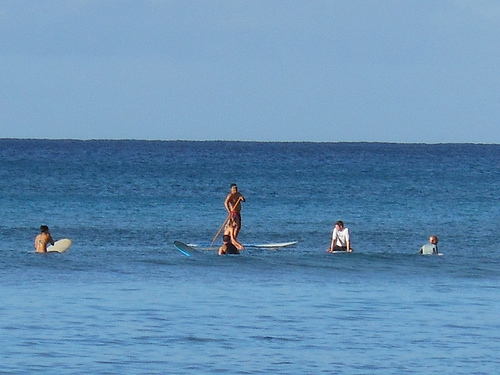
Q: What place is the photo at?
A: It is at the ocean.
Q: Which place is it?
A: It is an ocean.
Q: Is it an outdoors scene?
A: Yes, it is outdoors.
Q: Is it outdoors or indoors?
A: It is outdoors.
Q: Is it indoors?
A: No, it is outdoors.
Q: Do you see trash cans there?
A: No, there are no trash cans.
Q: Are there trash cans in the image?
A: No, there are no trash cans.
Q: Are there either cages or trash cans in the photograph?
A: No, there are no trash cans or cages.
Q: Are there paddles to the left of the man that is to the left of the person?
A: Yes, there is a paddle to the left of the man.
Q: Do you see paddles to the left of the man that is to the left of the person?
A: Yes, there is a paddle to the left of the man.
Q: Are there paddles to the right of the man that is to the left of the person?
A: No, the paddle is to the left of the man.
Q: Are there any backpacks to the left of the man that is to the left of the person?
A: No, there is a paddle to the left of the man.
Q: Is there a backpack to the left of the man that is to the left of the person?
A: No, there is a paddle to the left of the man.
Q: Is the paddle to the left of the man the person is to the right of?
A: Yes, the paddle is to the left of the man.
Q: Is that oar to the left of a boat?
A: No, the oar is to the left of the man.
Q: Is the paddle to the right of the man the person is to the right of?
A: No, the paddle is to the left of the man.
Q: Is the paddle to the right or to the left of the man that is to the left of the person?
A: The paddle is to the left of the man.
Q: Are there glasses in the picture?
A: No, there are no glasses.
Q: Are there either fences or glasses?
A: No, there are no glasses or fences.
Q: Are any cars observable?
A: No, there are no cars.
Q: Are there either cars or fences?
A: No, there are no cars or fences.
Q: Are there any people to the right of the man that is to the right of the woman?
A: Yes, there is a person to the right of the man.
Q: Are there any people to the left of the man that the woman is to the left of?
A: No, the person is to the right of the man.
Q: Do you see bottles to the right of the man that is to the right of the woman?
A: No, there is a person to the right of the man.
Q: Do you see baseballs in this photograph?
A: No, there are no baseballs.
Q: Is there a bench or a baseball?
A: No, there are no baseballs or benches.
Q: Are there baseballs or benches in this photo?
A: No, there are no baseballs or benches.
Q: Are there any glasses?
A: No, there are no glasses.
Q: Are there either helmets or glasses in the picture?
A: No, there are no glasses or helmets.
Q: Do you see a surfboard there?
A: Yes, there is a surfboard.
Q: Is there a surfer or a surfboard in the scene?
A: Yes, there is a surfboard.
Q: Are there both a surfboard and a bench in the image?
A: No, there is a surfboard but no benches.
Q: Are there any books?
A: No, there are no books.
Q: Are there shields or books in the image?
A: No, there are no books or shields.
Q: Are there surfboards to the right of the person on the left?
A: Yes, there is a surfboard to the right of the person.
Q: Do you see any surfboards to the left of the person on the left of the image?
A: No, the surfboard is to the right of the person.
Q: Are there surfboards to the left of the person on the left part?
A: No, the surfboard is to the right of the person.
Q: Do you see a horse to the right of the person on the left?
A: No, there is a surfboard to the right of the person.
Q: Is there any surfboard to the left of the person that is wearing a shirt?
A: Yes, there is a surfboard to the left of the person.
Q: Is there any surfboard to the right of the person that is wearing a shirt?
A: No, the surfboard is to the left of the person.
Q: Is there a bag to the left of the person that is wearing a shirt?
A: No, there is a surfboard to the left of the person.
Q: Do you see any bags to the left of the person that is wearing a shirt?
A: No, there is a surfboard to the left of the person.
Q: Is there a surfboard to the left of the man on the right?
A: Yes, there is a surfboard to the left of the man.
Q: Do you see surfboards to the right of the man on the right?
A: No, the surfboard is to the left of the man.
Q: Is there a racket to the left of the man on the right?
A: No, there is a surfboard to the left of the man.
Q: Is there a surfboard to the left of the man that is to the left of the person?
A: Yes, there is a surfboard to the left of the man.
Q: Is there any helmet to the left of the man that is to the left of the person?
A: No, there is a surfboard to the left of the man.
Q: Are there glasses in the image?
A: No, there are no glasses.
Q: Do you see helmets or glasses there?
A: No, there are no glasses or helmets.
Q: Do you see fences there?
A: No, there are no fences.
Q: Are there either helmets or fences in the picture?
A: No, there are no fences or helmets.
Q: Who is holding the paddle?
A: The man is holding the paddle.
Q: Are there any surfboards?
A: Yes, there is a surfboard.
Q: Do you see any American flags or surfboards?
A: Yes, there is a surfboard.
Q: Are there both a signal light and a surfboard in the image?
A: No, there is a surfboard but no traffic lights.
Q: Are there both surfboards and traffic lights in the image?
A: No, there is a surfboard but no traffic lights.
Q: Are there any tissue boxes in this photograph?
A: No, there are no tissue boxes.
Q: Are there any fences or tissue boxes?
A: No, there are no tissue boxes or fences.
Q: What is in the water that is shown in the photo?
A: The surfboard is in the water.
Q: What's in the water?
A: The surfboard is in the water.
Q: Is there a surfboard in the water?
A: Yes, there is a surfboard in the water.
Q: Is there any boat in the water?
A: No, there is a surfboard in the water.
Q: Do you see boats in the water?
A: No, there is a surfboard in the water.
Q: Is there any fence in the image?
A: No, there are no fences.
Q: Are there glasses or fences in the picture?
A: No, there are no fences or glasses.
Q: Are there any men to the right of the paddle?
A: Yes, there is a man to the right of the paddle.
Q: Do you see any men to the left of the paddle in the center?
A: No, the man is to the right of the oar.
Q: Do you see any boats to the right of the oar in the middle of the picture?
A: No, there is a man to the right of the oar.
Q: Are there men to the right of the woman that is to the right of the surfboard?
A: Yes, there is a man to the right of the woman.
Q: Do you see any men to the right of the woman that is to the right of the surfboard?
A: Yes, there is a man to the right of the woman.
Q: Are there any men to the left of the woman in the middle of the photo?
A: No, the man is to the right of the woman.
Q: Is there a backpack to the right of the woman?
A: No, there is a man to the right of the woman.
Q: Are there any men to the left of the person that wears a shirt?
A: Yes, there is a man to the left of the person.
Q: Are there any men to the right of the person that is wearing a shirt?
A: No, the man is to the left of the person.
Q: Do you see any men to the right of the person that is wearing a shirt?
A: No, the man is to the left of the person.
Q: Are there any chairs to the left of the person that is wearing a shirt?
A: No, there is a man to the left of the person.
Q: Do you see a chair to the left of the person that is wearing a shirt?
A: No, there is a man to the left of the person.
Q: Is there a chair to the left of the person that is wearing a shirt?
A: No, there is a man to the left of the person.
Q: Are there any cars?
A: No, there are no cars.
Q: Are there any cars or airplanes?
A: No, there are no cars or airplanes.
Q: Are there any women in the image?
A: Yes, there is a woman.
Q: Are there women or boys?
A: Yes, there is a woman.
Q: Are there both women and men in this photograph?
A: Yes, there are both a woman and a man.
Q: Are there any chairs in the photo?
A: No, there are no chairs.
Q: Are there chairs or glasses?
A: No, there are no chairs or glasses.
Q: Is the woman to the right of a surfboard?
A: Yes, the woman is to the right of a surfboard.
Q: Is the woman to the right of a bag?
A: No, the woman is to the right of a surfboard.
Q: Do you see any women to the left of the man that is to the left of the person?
A: Yes, there is a woman to the left of the man.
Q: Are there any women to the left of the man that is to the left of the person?
A: Yes, there is a woman to the left of the man.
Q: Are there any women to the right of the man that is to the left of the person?
A: No, the woman is to the left of the man.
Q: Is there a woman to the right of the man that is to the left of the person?
A: No, the woman is to the left of the man.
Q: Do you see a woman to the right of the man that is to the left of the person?
A: No, the woman is to the left of the man.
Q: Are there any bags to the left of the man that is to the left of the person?
A: No, there is a woman to the left of the man.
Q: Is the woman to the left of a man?
A: Yes, the woman is to the left of a man.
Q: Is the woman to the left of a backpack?
A: No, the woman is to the left of a man.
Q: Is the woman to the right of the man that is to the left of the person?
A: No, the woman is to the left of the man.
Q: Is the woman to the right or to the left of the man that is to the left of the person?
A: The woman is to the left of the man.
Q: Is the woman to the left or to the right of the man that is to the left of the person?
A: The woman is to the left of the man.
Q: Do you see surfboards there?
A: Yes, there is a surfboard.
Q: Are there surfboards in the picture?
A: Yes, there is a surfboard.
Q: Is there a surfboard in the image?
A: Yes, there is a surfboard.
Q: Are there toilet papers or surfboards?
A: Yes, there is a surfboard.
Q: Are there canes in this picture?
A: No, there are no canes.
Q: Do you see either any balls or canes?
A: No, there are no canes or balls.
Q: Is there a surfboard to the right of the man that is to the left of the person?
A: No, the surfboard is to the left of the man.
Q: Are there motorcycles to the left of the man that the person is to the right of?
A: No, there is a surfboard to the left of the man.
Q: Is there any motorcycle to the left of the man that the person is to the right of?
A: No, there is a surfboard to the left of the man.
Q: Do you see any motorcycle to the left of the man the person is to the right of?
A: No, there is a surfboard to the left of the man.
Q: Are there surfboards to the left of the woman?
A: Yes, there is a surfboard to the left of the woman.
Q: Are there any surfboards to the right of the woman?
A: No, the surfboard is to the left of the woman.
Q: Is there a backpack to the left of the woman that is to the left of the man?
A: No, there is a surfboard to the left of the woman.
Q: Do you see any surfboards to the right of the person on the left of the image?
A: Yes, there is a surfboard to the right of the person.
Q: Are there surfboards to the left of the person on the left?
A: No, the surfboard is to the right of the person.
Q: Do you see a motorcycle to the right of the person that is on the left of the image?
A: No, there is a surfboard to the right of the person.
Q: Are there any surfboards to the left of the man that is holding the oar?
A: Yes, there is a surfboard to the left of the man.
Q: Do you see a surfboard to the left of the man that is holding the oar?
A: Yes, there is a surfboard to the left of the man.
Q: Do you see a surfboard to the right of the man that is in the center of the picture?
A: No, the surfboard is to the left of the man.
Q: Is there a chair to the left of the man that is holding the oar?
A: No, there is a surfboard to the left of the man.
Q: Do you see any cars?
A: No, there are no cars.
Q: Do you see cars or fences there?
A: No, there are no cars or fences.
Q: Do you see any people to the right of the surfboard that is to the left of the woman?
A: No, the person is to the left of the surf board.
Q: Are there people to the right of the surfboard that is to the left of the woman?
A: No, the person is to the left of the surf board.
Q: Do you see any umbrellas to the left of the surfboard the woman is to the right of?
A: No, there is a person to the left of the surf board.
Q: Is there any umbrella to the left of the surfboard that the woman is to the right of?
A: No, there is a person to the left of the surf board.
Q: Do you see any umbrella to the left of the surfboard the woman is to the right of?
A: No, there is a person to the left of the surf board.